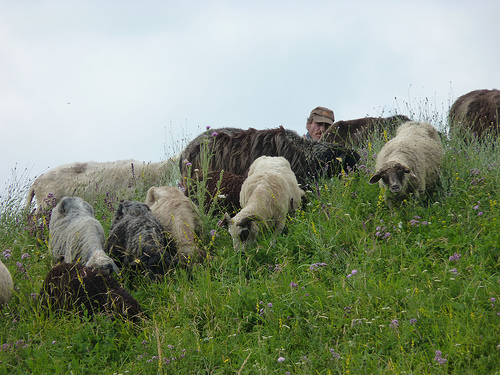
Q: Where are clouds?
A: In the sky.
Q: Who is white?
A: Sheep.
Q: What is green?
A: Grass.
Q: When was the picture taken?
A: Daytime.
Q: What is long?
A: The grass.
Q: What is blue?
A: Sky.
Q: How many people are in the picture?
A: One.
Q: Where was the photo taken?
A: On a grassy rural hill.